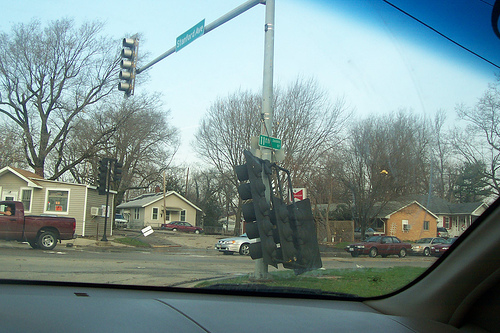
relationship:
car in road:
[345, 232, 415, 257] [0, 228, 439, 288]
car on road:
[215, 228, 262, 260] [5, 238, 443, 294]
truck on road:
[3, 193, 81, 251] [5, 238, 443, 294]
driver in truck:
[0, 201, 14, 218] [1, 196, 77, 254]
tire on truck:
[31, 224, 60, 249] [1, 196, 77, 254]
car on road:
[343, 230, 415, 258] [4, 230, 449, 287]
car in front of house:
[163, 216, 205, 234] [114, 188, 204, 238]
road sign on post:
[255, 131, 284, 155] [260, 3, 285, 171]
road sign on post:
[174, 17, 205, 53] [134, 1, 275, 76]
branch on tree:
[298, 133, 351, 178] [255, 84, 336, 214]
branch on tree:
[331, 162, 351, 186] [335, 153, 375, 225]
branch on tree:
[280, 94, 317, 174] [238, 85, 329, 210]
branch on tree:
[328, 137, 344, 167] [318, 134, 348, 182]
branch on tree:
[278, 82, 318, 162] [254, 76, 334, 195]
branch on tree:
[213, 106, 236, 149] [217, 93, 264, 184]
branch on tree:
[153, 112, 172, 142] [76, 106, 160, 227]